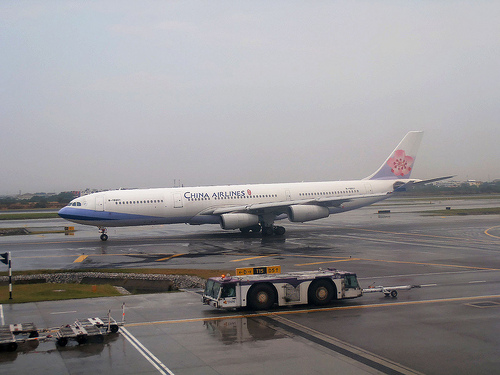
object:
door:
[95, 197, 105, 212]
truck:
[200, 266, 363, 309]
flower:
[385, 149, 414, 177]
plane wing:
[210, 192, 392, 215]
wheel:
[307, 276, 337, 306]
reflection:
[201, 304, 293, 346]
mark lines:
[123, 294, 500, 327]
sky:
[0, 3, 497, 198]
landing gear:
[98, 232, 107, 242]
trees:
[477, 179, 499, 195]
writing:
[184, 191, 210, 199]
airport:
[0, 0, 499, 374]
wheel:
[245, 283, 279, 311]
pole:
[8, 250, 13, 298]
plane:
[57, 129, 458, 241]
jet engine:
[219, 212, 262, 230]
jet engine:
[287, 204, 328, 221]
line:
[57, 211, 119, 222]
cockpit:
[66, 196, 86, 210]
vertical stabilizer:
[360, 130, 420, 181]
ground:
[0, 193, 499, 373]